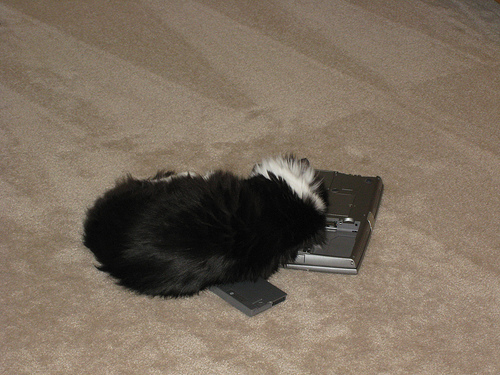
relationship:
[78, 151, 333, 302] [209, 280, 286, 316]
animal on battery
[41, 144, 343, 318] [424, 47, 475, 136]
dog on carpet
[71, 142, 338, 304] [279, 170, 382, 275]
dog on laptop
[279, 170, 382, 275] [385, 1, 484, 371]
laptop on carpet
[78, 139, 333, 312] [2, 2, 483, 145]
dog on carpet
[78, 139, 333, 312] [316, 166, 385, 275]
dog on laptop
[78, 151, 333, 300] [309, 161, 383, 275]
dog on battery pack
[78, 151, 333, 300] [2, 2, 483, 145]
dog on carpet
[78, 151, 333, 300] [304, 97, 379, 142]
dog on ground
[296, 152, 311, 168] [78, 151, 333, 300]
nose on dog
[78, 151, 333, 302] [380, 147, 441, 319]
animal on floor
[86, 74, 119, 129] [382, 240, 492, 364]
carpet on floor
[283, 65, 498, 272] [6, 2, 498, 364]
marks on floor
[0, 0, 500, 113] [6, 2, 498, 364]
marks on floor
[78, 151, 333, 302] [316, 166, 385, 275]
animal on laptop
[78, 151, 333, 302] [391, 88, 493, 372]
animal sleeping on carpet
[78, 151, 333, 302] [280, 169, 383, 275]
animal on device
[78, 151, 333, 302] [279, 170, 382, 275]
animal sleeping on laptop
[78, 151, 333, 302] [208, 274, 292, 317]
animal sleeping on cell phone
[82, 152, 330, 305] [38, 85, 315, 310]
fur of cat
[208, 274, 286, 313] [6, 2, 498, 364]
cell phone on floor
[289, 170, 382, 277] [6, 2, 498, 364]
laptop on floor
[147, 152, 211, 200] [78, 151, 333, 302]
leg of animal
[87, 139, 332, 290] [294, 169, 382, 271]
animal sits on device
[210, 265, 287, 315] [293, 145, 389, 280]
battery taken out of laptop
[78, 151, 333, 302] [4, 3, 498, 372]
animal inside room